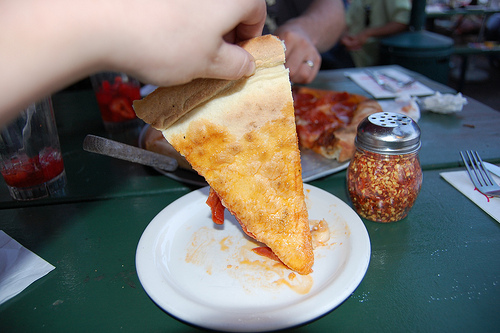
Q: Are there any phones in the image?
A: No, there are no phones.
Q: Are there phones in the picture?
A: No, there are no phones.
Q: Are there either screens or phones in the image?
A: No, there are no phones or screens.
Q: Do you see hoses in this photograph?
A: No, there are no hoses.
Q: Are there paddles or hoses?
A: No, there are no hoses or paddles.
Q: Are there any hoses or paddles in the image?
A: No, there are no hoses or paddles.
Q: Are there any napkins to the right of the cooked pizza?
A: Yes, there is a napkin to the right of the pizza.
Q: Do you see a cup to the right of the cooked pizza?
A: No, there is a napkin to the right of the pizza.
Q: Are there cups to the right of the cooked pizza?
A: No, there is a napkin to the right of the pizza.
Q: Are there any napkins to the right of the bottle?
A: Yes, there is a napkin to the right of the bottle.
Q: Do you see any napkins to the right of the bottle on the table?
A: Yes, there is a napkin to the right of the bottle.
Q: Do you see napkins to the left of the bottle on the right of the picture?
A: No, the napkin is to the right of the bottle.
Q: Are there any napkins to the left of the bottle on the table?
A: No, the napkin is to the right of the bottle.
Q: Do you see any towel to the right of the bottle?
A: No, there is a napkin to the right of the bottle.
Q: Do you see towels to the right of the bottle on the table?
A: No, there is a napkin to the right of the bottle.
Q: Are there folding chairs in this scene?
A: No, there are no folding chairs.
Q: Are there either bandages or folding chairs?
A: No, there are no folding chairs or bandages.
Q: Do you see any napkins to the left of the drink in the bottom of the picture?
A: Yes, there is a napkin to the left of the juice.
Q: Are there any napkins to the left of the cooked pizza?
A: Yes, there is a napkin to the left of the pizza.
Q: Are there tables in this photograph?
A: Yes, there is a table.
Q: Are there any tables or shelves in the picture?
A: Yes, there is a table.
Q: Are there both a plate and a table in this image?
A: Yes, there are both a table and a plate.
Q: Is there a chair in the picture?
A: No, there are no chairs.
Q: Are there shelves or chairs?
A: No, there are no chairs or shelves.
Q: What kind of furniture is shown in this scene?
A: The furniture is a table.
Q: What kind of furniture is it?
A: The piece of furniture is a table.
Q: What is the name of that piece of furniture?
A: This is a table.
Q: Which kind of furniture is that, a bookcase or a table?
A: This is a table.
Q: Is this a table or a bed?
A: This is a table.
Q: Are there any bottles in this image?
A: Yes, there is a bottle.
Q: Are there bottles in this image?
A: Yes, there is a bottle.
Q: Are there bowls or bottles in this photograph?
A: Yes, there is a bottle.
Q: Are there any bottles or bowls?
A: Yes, there is a bottle.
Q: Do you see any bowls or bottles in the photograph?
A: Yes, there is a bottle.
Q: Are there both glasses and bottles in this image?
A: Yes, there are both a bottle and glasses.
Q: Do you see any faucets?
A: No, there are no faucets.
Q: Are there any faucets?
A: No, there are no faucets.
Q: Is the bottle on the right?
A: Yes, the bottle is on the right of the image.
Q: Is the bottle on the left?
A: No, the bottle is on the right of the image.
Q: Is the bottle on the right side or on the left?
A: The bottle is on the right of the image.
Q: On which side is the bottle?
A: The bottle is on the right of the image.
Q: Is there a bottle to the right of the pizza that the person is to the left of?
A: Yes, there is a bottle to the right of the pizza.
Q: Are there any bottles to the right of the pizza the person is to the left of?
A: Yes, there is a bottle to the right of the pizza.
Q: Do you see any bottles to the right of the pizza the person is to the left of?
A: Yes, there is a bottle to the right of the pizza.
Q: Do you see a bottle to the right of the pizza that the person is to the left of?
A: Yes, there is a bottle to the right of the pizza.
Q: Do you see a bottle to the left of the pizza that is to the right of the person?
A: No, the bottle is to the right of the pizza.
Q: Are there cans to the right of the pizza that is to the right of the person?
A: No, there is a bottle to the right of the pizza.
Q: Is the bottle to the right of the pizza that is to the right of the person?
A: Yes, the bottle is to the right of the pizza.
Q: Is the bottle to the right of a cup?
A: No, the bottle is to the right of the pizza.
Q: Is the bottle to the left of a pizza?
A: No, the bottle is to the right of a pizza.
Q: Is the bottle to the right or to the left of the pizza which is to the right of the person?
A: The bottle is to the right of the pizza.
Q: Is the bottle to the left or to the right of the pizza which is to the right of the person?
A: The bottle is to the right of the pizza.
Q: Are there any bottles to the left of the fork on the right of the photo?
A: Yes, there is a bottle to the left of the fork.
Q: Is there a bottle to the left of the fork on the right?
A: Yes, there is a bottle to the left of the fork.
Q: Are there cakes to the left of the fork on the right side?
A: No, there is a bottle to the left of the fork.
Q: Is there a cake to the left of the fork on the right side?
A: No, there is a bottle to the left of the fork.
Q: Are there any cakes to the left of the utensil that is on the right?
A: No, there is a bottle to the left of the fork.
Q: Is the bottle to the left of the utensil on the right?
A: Yes, the bottle is to the left of the fork.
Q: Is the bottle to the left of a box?
A: No, the bottle is to the left of the fork.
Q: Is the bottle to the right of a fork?
A: No, the bottle is to the left of a fork.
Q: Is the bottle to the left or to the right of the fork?
A: The bottle is to the left of the fork.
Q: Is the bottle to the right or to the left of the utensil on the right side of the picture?
A: The bottle is to the left of the fork.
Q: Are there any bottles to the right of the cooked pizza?
A: Yes, there is a bottle to the right of the pizza.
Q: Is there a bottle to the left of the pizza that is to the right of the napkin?
A: No, the bottle is to the right of the pizza.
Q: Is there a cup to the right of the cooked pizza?
A: No, there is a bottle to the right of the pizza.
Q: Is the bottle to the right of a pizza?
A: Yes, the bottle is to the right of a pizza.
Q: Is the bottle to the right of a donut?
A: No, the bottle is to the right of a pizza.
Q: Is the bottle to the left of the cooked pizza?
A: No, the bottle is to the right of the pizza.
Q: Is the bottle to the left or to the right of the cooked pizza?
A: The bottle is to the right of the pizza.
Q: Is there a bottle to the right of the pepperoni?
A: Yes, there is a bottle to the right of the pepperoni.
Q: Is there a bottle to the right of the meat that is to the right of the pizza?
A: Yes, there is a bottle to the right of the pepperoni.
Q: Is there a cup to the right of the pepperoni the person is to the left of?
A: No, there is a bottle to the right of the pepperoni.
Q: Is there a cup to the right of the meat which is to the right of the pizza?
A: No, there is a bottle to the right of the pepperoni.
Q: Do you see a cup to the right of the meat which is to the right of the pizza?
A: No, there is a bottle to the right of the pepperoni.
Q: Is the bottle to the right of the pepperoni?
A: Yes, the bottle is to the right of the pepperoni.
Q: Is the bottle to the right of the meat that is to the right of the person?
A: Yes, the bottle is to the right of the pepperoni.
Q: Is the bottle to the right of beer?
A: No, the bottle is to the right of the pepperoni.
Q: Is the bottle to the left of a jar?
A: No, the bottle is to the left of the napkin.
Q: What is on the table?
A: The bottle is on the table.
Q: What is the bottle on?
A: The bottle is on the table.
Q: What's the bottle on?
A: The bottle is on the table.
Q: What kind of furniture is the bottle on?
A: The bottle is on the table.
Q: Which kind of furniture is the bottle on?
A: The bottle is on the table.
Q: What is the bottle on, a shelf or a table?
A: The bottle is on a table.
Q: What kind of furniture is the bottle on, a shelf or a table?
A: The bottle is on a table.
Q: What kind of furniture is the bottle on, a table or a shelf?
A: The bottle is on a table.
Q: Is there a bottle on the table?
A: Yes, there is a bottle on the table.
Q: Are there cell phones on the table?
A: No, there is a bottle on the table.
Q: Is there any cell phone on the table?
A: No, there is a bottle on the table.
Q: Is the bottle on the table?
A: Yes, the bottle is on the table.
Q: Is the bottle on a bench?
A: No, the bottle is on the table.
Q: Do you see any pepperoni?
A: Yes, there is pepperoni.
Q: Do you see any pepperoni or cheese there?
A: Yes, there is pepperoni.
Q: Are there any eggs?
A: No, there are no eggs.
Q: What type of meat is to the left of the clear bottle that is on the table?
A: The meat is pepperoni.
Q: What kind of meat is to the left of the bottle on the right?
A: The meat is pepperoni.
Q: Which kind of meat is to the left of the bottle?
A: The meat is pepperoni.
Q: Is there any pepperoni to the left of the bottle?
A: Yes, there is pepperoni to the left of the bottle.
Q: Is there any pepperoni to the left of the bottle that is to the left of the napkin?
A: Yes, there is pepperoni to the left of the bottle.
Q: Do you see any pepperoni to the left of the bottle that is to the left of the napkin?
A: Yes, there is pepperoni to the left of the bottle.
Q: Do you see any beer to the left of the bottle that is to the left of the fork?
A: No, there is pepperoni to the left of the bottle.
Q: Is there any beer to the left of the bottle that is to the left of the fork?
A: No, there is pepperoni to the left of the bottle.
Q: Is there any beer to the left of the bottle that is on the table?
A: No, there is pepperoni to the left of the bottle.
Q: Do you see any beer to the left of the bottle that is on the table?
A: No, there is pepperoni to the left of the bottle.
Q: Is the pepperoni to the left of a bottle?
A: Yes, the pepperoni is to the left of a bottle.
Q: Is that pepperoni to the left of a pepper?
A: No, the pepperoni is to the left of a bottle.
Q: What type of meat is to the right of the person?
A: The meat is pepperoni.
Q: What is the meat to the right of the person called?
A: The meat is pepperoni.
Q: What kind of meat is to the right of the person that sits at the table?
A: The meat is pepperoni.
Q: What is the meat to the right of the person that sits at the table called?
A: The meat is pepperoni.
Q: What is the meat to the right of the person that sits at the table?
A: The meat is pepperoni.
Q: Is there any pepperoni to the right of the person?
A: Yes, there is pepperoni to the right of the person.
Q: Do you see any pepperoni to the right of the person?
A: Yes, there is pepperoni to the right of the person.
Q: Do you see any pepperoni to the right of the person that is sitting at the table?
A: Yes, there is pepperoni to the right of the person.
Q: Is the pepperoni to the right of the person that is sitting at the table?
A: Yes, the pepperoni is to the right of the person.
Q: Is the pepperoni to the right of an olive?
A: No, the pepperoni is to the right of the person.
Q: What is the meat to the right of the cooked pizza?
A: The meat is pepperoni.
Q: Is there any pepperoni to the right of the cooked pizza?
A: Yes, there is pepperoni to the right of the pizza.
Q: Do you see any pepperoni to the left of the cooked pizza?
A: No, the pepperoni is to the right of the pizza.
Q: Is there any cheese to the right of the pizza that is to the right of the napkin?
A: No, there is pepperoni to the right of the pizza.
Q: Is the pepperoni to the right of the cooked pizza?
A: Yes, the pepperoni is to the right of the pizza.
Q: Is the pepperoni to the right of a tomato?
A: No, the pepperoni is to the right of the pizza.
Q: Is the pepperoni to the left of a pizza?
A: No, the pepperoni is to the right of a pizza.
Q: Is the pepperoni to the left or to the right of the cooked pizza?
A: The pepperoni is to the right of the pizza.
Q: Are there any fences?
A: No, there are no fences.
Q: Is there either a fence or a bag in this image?
A: No, there are no fences or bags.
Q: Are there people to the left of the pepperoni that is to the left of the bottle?
A: Yes, there is a person to the left of the pepperoni.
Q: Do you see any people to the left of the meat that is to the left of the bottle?
A: Yes, there is a person to the left of the pepperoni.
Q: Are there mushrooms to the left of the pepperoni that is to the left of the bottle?
A: No, there is a person to the left of the pepperoni.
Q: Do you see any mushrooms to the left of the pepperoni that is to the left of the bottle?
A: No, there is a person to the left of the pepperoni.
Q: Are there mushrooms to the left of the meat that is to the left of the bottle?
A: No, there is a person to the left of the pepperoni.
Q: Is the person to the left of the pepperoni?
A: Yes, the person is to the left of the pepperoni.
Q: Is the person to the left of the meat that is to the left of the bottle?
A: Yes, the person is to the left of the pepperoni.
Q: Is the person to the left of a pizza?
A: Yes, the person is to the left of a pizza.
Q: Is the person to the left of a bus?
A: No, the person is to the left of a pizza.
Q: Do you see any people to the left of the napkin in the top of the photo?
A: Yes, there is a person to the left of the napkin.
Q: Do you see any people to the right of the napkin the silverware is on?
A: No, the person is to the left of the napkin.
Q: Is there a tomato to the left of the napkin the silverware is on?
A: No, there is a person to the left of the napkin.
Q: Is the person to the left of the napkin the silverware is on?
A: Yes, the person is to the left of the napkin.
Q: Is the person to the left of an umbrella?
A: No, the person is to the left of the napkin.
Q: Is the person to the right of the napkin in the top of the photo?
A: No, the person is to the left of the napkin.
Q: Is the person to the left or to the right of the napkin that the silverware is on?
A: The person is to the left of the napkin.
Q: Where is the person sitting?
A: The person is sitting at the table.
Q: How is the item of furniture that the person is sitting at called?
A: The piece of furniture is a table.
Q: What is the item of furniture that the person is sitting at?
A: The piece of furniture is a table.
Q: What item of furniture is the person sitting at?
A: The person is sitting at the table.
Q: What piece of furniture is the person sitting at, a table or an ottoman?
A: The person is sitting at a table.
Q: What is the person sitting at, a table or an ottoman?
A: The person is sitting at a table.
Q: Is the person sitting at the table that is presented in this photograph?
A: Yes, the person is sitting at the table.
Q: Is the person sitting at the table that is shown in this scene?
A: Yes, the person is sitting at the table.